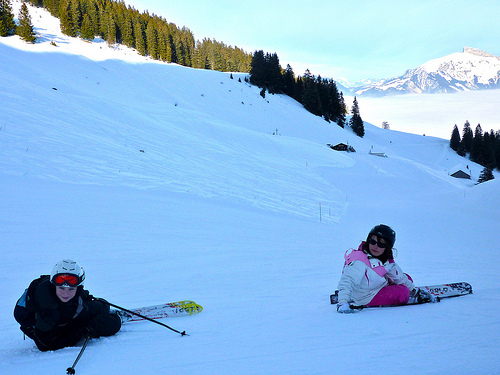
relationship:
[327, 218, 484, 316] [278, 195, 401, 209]
girl on ground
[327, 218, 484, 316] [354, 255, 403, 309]
girl in pink & white jacket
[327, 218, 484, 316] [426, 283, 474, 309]
girl wearing skis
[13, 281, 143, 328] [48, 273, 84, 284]
boy in red googles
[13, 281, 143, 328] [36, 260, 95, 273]
boy in white helmet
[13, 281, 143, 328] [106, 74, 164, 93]
boy on snow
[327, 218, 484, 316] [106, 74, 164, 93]
girl on snow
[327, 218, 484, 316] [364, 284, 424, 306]
girl in pants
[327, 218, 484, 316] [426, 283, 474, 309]
girl on skis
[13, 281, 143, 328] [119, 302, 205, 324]
boy leaning over skis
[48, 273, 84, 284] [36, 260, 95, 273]
red googles on white helmet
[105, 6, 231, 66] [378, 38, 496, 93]
trees on mountain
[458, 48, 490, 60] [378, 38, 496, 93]
ledge on mountain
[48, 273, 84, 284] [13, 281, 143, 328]
red googles on boy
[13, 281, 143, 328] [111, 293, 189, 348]
boy holding ski poles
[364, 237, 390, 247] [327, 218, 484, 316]
sunglasses on girl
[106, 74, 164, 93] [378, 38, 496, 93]
snow on mountain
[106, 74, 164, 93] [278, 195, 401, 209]
snow on ground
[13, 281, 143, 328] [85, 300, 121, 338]
boy in black pants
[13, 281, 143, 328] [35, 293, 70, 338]
boy in black jacket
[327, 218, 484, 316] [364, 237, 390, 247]
girl wearing sunglasses